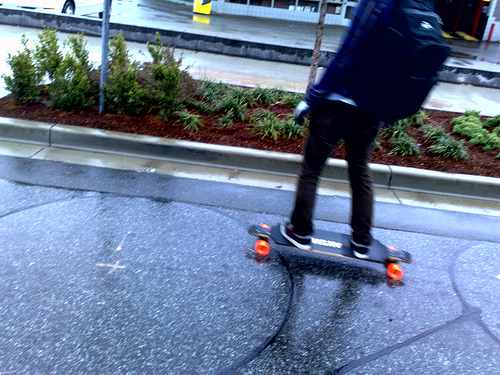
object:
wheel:
[386, 262, 405, 280]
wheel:
[254, 239, 271, 256]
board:
[248, 223, 413, 283]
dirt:
[6, 71, 499, 171]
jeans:
[293, 97, 381, 247]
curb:
[1, 115, 498, 200]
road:
[1, 137, 498, 374]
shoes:
[278, 221, 312, 250]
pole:
[94, 2, 115, 114]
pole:
[304, 0, 331, 87]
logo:
[419, 20, 434, 30]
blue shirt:
[301, 0, 380, 111]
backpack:
[356, 2, 453, 125]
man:
[279, 0, 455, 261]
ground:
[0, 137, 499, 372]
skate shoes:
[349, 238, 370, 261]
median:
[0, 18, 499, 198]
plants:
[4, 28, 287, 142]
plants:
[380, 107, 500, 148]